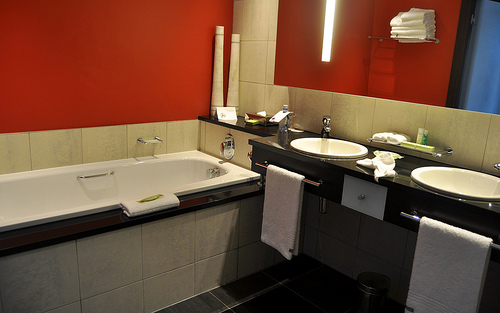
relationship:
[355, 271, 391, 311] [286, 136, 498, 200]
garbage can under sink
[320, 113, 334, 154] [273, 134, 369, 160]
faucet on sink cabinet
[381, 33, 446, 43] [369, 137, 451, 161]
towels on shelf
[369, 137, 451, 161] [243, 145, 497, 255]
shelf above cabinet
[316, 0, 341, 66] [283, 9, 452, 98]
light on wall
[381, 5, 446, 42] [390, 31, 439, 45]
towels folded on wall rack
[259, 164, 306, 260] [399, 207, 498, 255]
towel on rack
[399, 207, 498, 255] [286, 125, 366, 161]
rack by sink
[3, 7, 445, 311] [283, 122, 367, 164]
bathroom has sink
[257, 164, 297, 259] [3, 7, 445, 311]
towell in bathroom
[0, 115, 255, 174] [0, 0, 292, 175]
tiling on wall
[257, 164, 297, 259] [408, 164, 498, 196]
towell on sink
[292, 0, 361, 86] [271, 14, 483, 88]
light on mirror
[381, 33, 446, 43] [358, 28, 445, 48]
towels on shelf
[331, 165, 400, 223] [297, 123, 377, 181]
drawer on sink